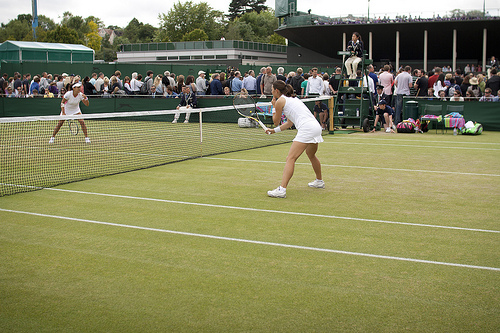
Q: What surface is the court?
A: Grass.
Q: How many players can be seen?
A: Two.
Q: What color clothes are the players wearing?
A: White.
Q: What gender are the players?
A: Female.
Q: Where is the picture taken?
A: At a tennis tournament.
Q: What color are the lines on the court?
A: White.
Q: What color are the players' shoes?
A: White.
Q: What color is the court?
A: Green.